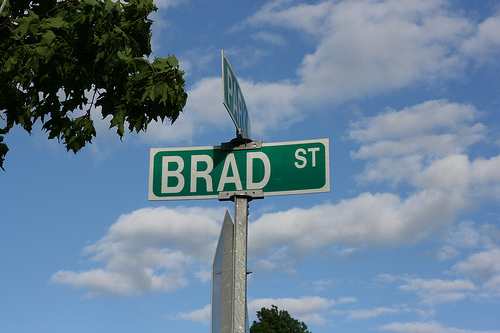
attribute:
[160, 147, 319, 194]
lettering — white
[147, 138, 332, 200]
sign — green, white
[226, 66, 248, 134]
lettering — white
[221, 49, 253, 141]
sign — green, white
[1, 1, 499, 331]
sky — light blue, cloudy, blue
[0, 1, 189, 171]
tree — green, leafy, tall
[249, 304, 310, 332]
tree — green, leafy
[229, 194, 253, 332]
pole — metal, gray, silver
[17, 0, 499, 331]
clouds — white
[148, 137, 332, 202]
border — white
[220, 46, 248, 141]
border — white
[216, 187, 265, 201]
clasp — grey, metal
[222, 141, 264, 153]
clasp — grey, metal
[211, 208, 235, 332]
sign — gray